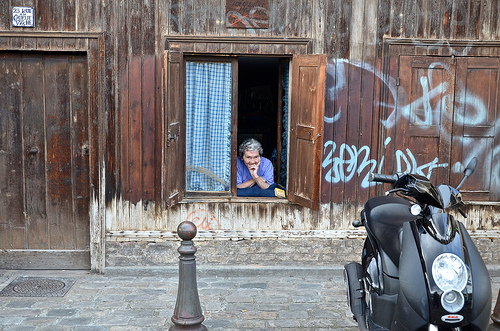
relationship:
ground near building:
[101, 267, 355, 327] [2, 0, 498, 250]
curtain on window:
[183, 59, 235, 195] [155, 47, 316, 205]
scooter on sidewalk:
[342, 168, 492, 329] [5, 270, 493, 324]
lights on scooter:
[427, 245, 469, 315] [342, 168, 492, 329]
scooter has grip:
[342, 168, 492, 329] [366, 170, 399, 185]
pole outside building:
[151, 208, 241, 320] [2, 0, 498, 250]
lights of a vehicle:
[427, 245, 469, 315] [352, 164, 492, 302]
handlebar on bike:
[370, 170, 404, 189] [345, 159, 493, 328]